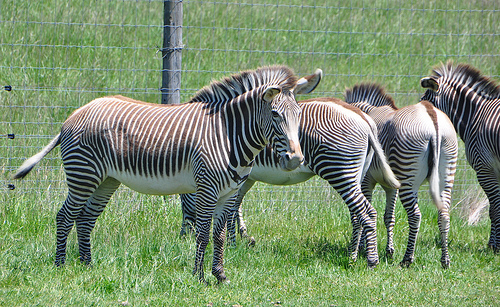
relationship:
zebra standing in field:
[13, 63, 322, 285] [1, 0, 496, 305]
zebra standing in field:
[13, 63, 322, 285] [0, 183, 500, 303]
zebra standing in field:
[13, 63, 322, 285] [10, 7, 490, 58]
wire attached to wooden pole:
[1, 16, 498, 38] [159, 2, 185, 100]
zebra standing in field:
[162, 77, 407, 274] [1, 0, 496, 305]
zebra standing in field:
[340, 80, 457, 270] [1, 0, 496, 305]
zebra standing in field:
[419, 52, 499, 256] [1, 0, 496, 305]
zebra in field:
[13, 63, 322, 285] [0, 183, 500, 303]